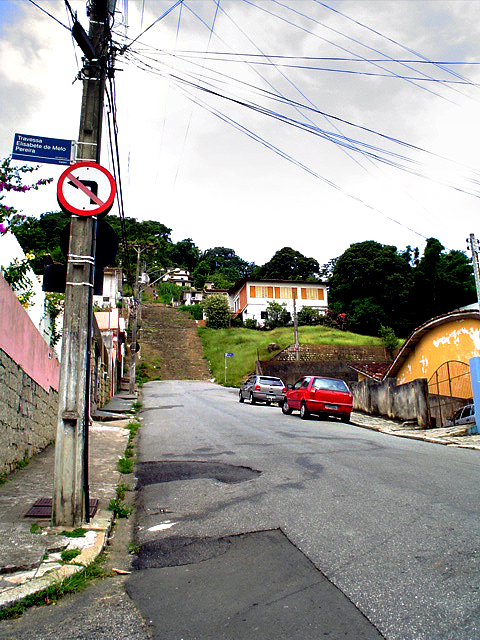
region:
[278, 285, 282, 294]
glass window on the building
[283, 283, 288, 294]
glass window on the building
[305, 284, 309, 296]
glass window on the building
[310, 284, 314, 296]
glass window on the building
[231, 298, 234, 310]
glass window on the building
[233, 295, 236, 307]
glass window on the building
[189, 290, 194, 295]
glass window on the building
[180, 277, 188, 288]
glass window on the building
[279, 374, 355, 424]
red car parked on the street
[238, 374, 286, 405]
silver car parked on the street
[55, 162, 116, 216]
sign is red and white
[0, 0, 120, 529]
power pole is on the sidewalk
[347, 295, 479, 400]
house is orange and white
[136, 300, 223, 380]
road is made of dirt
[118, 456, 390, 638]
road has repair patchwork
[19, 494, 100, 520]
brown metal grate in the sidewalk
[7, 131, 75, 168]
sign is blue and white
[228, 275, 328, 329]
house is orange and white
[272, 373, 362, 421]
red car parked on the street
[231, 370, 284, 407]
gray car parked on the street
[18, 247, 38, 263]
yellow flower on the bush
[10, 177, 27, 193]
purple flower on the bush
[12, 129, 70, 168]
street sign in is blue and white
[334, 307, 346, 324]
red flowers on the bush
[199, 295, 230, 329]
bush in front of the house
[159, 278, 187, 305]
bush in front of the house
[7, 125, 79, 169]
sign on a pole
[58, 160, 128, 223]
sign on a pole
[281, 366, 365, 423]
car on a street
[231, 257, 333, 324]
house on a hill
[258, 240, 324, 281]
tree near a home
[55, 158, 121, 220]
No left turn sign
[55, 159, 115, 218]
White and red circular sign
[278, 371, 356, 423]
Small red hatchback style car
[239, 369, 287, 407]
small gray hatchback style car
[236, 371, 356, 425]
Two cars parked on the slope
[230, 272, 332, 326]
White house with orange accents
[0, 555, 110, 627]
Grass growing between sidewalk and street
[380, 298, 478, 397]
Orange building with paint coming off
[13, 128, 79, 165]
Blue street sign with name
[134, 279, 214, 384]
Dirt street going up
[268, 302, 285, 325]
A tree in a city.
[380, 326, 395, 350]
A tree in a city.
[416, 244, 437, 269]
A tree in a city.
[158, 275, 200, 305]
A tree in a city.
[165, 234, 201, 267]
A tree in a city.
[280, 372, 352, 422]
red car parked on a curb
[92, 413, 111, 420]
purple storm drain on a side walk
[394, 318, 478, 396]
dark yellow side of a building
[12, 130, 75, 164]
blue sign with white letters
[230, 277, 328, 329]
large white and orange house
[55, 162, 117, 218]
round no turns sign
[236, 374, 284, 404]
silver car on a curb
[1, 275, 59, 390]
pink wall above a rock wall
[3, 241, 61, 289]
large plant with yellow flowers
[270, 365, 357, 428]
red hatchback car on road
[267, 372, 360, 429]
red hatchback car on road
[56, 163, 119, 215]
a "no left turn" sign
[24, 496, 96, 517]
a grate in the sidewalk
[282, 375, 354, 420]
a compact red car